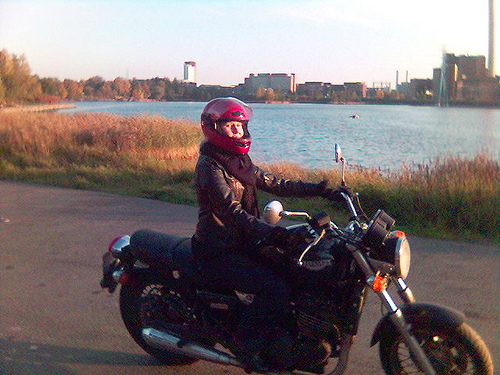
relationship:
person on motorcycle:
[187, 103, 298, 367] [97, 148, 499, 374]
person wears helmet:
[187, 103, 298, 367] [204, 98, 251, 154]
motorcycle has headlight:
[97, 148, 499, 374] [391, 226, 408, 280]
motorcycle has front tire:
[97, 148, 499, 374] [379, 307, 500, 374]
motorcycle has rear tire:
[97, 148, 499, 374] [118, 272, 217, 359]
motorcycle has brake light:
[97, 148, 499, 374] [107, 234, 126, 254]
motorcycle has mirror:
[97, 148, 499, 374] [266, 191, 308, 222]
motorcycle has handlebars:
[97, 148, 499, 374] [263, 221, 314, 239]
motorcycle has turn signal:
[97, 148, 499, 374] [302, 224, 326, 267]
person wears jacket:
[187, 103, 298, 367] [193, 155, 316, 237]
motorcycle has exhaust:
[97, 148, 499, 374] [141, 332, 233, 361]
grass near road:
[11, 115, 189, 191] [4, 180, 496, 373]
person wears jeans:
[187, 103, 298, 367] [213, 257, 298, 349]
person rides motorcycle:
[187, 103, 298, 367] [97, 148, 499, 374]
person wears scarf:
[187, 103, 298, 367] [207, 148, 257, 214]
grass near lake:
[11, 115, 189, 191] [57, 101, 500, 177]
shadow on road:
[6, 349, 167, 368] [4, 180, 496, 373]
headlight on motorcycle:
[391, 226, 408, 280] [97, 148, 499, 374]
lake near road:
[57, 101, 500, 177] [4, 180, 496, 373]